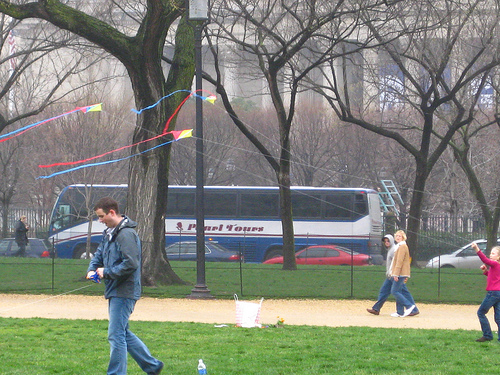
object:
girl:
[467, 236, 499, 348]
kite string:
[107, 99, 499, 254]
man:
[85, 197, 164, 374]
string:
[1, 272, 105, 317]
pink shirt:
[468, 235, 498, 295]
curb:
[415, 257, 428, 271]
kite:
[0, 77, 395, 235]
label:
[198, 365, 203, 368]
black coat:
[85, 218, 158, 303]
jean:
[101, 295, 163, 373]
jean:
[476, 291, 498, 345]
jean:
[371, 272, 418, 320]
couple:
[362, 227, 425, 324]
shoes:
[388, 302, 425, 321]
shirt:
[391, 237, 420, 279]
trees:
[1, 0, 499, 287]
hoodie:
[388, 227, 411, 285]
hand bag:
[227, 286, 269, 339]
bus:
[48, 178, 390, 260]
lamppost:
[171, 6, 235, 291]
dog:
[225, 289, 276, 333]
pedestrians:
[364, 226, 421, 326]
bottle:
[195, 353, 207, 373]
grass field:
[0, 318, 499, 368]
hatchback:
[6, 231, 58, 256]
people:
[3, 166, 498, 373]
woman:
[382, 230, 424, 312]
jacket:
[394, 237, 414, 280]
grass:
[2, 246, 497, 370]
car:
[261, 242, 381, 272]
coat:
[387, 242, 420, 282]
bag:
[225, 287, 270, 330]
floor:
[5, 245, 471, 373]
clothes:
[89, 213, 169, 368]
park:
[6, 3, 497, 373]